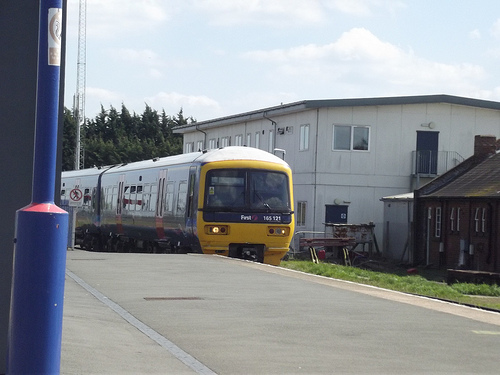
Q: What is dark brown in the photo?
A: House.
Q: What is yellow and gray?
A: Train.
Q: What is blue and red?
A: Post.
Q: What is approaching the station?
A: A train.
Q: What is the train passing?
A: A building.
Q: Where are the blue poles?
A: On the cement ground.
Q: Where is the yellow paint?
A: On the train.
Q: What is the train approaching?
A: The concrete platform.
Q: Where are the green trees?
A: Behind the building.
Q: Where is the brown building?
A: Next to the light colored building.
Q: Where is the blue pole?
A: On the platform.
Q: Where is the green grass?
A: Next to the buildings.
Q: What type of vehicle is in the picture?
A: A train.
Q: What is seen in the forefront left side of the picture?
A: A blue pole.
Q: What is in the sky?
A: Clouds.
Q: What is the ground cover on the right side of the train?
A: Pavement.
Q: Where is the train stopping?
A: At the train station.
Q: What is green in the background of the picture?
A: Trees.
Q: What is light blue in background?
A: The sky.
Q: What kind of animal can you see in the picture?
A: No animals.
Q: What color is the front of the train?
A: Yellow.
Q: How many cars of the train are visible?
A: Two.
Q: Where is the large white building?
A: Beside the train.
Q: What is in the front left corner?
A: A pole.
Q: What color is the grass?
A: Green.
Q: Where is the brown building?
A: In front of the white building.